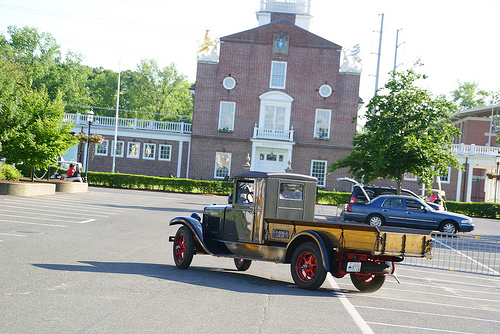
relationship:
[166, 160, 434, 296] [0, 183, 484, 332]
car parked in lot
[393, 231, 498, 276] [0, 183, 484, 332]
railing in lot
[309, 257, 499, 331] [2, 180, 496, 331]
white lines on parking lot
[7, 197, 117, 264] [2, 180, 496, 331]
white lines on parking lot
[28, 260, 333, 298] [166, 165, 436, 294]
shadow of truck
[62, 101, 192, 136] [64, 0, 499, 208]
railing on brick buildnig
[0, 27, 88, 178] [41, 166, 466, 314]
tree in parking lot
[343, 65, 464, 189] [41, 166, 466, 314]
tree in parking lot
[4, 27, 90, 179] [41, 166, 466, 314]
tree in parking lot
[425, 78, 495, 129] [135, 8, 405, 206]
tree behind brick building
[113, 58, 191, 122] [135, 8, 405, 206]
tree behind brick building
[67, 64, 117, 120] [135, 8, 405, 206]
tree behind brick building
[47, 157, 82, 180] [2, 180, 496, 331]
golf cart through parking lot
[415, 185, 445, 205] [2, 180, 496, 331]
golf cart through parking lot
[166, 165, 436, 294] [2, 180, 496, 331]
truck through parking lot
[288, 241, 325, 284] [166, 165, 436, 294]
tire on a truck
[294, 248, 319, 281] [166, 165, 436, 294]
red rim on a truck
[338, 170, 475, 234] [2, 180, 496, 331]
blue car on a parking lot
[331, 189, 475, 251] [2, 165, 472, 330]
car in parking lot